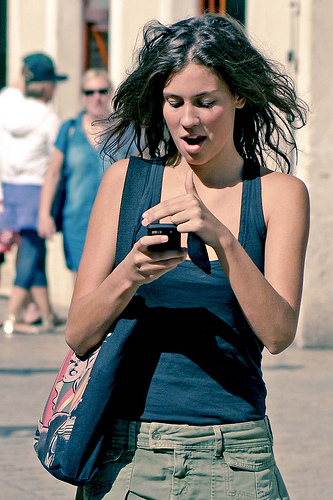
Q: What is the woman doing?
A: Using her phone.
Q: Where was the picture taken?
A: A busy street.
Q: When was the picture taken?
A: During daylight hours.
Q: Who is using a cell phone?
A: A woman.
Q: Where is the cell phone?
A: In the girl's hands.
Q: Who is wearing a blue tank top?
A: The woman on the cell phone.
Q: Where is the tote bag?
A: On the woman's shoulder.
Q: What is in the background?
A: People on a city street.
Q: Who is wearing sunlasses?
A: Woman in the blue dress.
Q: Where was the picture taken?
A: On a sidewalk.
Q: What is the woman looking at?
A: Her phone.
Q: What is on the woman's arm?
A: A bag.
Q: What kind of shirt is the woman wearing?
A: Tank top.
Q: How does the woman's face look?
A: Surprised.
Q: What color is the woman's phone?
A: Black.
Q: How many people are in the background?
A: 3.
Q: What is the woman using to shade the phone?
A: A hand.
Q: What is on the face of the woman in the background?
A: Sunglasses.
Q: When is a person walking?
A: Now.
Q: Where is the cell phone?
A: Woman's hand.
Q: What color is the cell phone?
A: Black.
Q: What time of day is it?
A: Day time.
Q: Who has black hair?
A: Woman in black hair.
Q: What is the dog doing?
A: No dog.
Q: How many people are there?
A: Four.